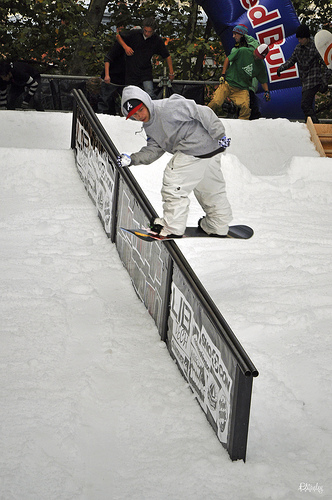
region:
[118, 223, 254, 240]
the snow board under the man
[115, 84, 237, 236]
the man on the snow board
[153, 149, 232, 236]
the light colored pants on the man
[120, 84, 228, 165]
the gray sweatshirt on the man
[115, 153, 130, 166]
the glove on the man's right hand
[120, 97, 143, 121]
the hat on the man's head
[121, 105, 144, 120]
the red rim of the man's hat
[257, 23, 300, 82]
the word Bull in red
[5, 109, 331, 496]
the white snow on the ground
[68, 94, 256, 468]
the wall beneath the man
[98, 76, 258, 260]
the man is snowboarding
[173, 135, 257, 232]
man's pants are white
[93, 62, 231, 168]
man's jacket is gray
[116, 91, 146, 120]
man wearing a hat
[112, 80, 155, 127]
man's hoodie over hat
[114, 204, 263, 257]
man's snowboard is black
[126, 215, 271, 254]
snowboard is on a ramp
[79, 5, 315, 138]
people snowboarding in background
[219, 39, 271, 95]
man's shirt is green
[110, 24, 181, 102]
man's shirt is black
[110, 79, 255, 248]
This is a person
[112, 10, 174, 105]
This is a person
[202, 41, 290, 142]
This is a person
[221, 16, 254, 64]
This is a person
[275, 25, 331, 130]
This is a person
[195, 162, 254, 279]
Leg of a person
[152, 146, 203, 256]
Leg of a person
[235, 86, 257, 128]
Leg of a person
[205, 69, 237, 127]
Leg of a person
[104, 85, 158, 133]
Head of a person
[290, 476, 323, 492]
part of a graphic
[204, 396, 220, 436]
part of a fence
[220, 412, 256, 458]
part of a fence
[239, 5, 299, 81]
A Red Bull logo behind a group of people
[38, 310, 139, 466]
Snow beneath the snowboarder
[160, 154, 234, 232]
The snowboarder is wearing pants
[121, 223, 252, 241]
A snowboard on a rail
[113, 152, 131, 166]
The right hand of the snowboarder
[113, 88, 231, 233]
A person above the snow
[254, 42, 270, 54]
The man in green has a hat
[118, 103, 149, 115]
The snowboarder is wearing a hat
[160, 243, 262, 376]
A rail under the snowboard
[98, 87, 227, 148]
The snowboarder has a white sweater